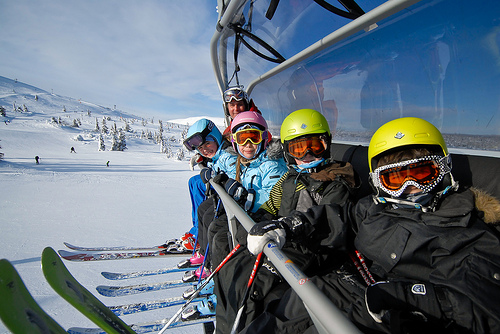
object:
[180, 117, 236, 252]
girl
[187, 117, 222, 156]
helmet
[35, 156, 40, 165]
people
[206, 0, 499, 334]
lift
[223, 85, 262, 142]
skier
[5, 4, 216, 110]
cloud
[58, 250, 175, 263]
ski poles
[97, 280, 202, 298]
ski poles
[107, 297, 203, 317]
ski poles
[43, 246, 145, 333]
ski poles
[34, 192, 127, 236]
ground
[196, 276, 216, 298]
boots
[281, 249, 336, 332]
plastic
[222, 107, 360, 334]
kid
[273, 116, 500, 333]
kid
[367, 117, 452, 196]
helmet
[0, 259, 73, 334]
board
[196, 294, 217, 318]
boot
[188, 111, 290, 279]
girl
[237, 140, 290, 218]
jacket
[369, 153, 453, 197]
glass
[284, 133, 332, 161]
glass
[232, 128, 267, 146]
glass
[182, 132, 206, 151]
glass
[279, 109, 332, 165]
helmet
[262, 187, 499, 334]
clothing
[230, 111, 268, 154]
helmet